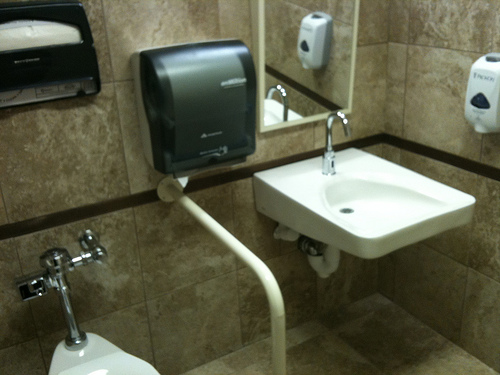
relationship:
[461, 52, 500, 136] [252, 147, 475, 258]
container near sink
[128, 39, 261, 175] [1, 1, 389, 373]
container on bathroom wall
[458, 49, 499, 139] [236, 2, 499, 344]
container attached to wall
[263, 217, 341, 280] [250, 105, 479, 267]
pipe under sink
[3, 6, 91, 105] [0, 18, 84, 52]
container for cover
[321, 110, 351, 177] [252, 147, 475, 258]
faucet attached to sink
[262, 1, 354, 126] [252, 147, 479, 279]
mirror above sink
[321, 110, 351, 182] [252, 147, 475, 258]
faucet on sink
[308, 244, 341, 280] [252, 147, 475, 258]
pipe below sink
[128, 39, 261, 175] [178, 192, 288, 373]
container below bar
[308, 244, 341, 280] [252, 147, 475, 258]
pipe under sink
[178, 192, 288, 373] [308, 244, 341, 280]
bar near pipe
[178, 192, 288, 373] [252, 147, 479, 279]
bar next to sink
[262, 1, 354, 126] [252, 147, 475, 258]
mirror above sink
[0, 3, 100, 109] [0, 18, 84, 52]
dispenser holding cover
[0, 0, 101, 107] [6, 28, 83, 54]
container has cover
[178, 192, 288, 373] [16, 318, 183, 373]
bar beside toilet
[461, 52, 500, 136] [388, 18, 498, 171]
container on wall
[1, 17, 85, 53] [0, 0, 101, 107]
toiler seat on container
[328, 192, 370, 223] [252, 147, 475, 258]
drain in sink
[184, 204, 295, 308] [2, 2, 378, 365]
bar attached to wall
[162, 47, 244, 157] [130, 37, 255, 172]
towel inside container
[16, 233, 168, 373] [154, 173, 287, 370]
toilet next to rail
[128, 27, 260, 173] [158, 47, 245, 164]
container holds towel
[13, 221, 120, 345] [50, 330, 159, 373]
plumbing of toilet